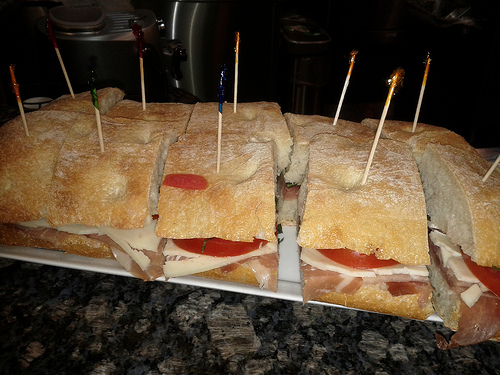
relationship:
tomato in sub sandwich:
[176, 237, 273, 260] [156, 114, 285, 305]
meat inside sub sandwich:
[167, 259, 282, 283] [156, 114, 285, 305]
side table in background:
[265, 12, 351, 119] [13, 6, 494, 113]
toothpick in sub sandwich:
[208, 56, 237, 176] [156, 114, 285, 305]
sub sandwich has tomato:
[156, 114, 285, 305] [176, 237, 273, 260]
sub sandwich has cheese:
[156, 114, 285, 305] [170, 243, 275, 278]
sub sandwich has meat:
[156, 114, 285, 305] [167, 259, 282, 283]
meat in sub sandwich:
[167, 259, 282, 283] [156, 114, 285, 305]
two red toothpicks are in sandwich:
[33, 10, 161, 116] [2, 41, 499, 344]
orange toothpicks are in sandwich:
[213, 26, 440, 199] [2, 41, 499, 344]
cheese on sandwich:
[170, 243, 275, 278] [2, 41, 499, 344]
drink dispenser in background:
[154, 4, 241, 110] [13, 6, 494, 113]